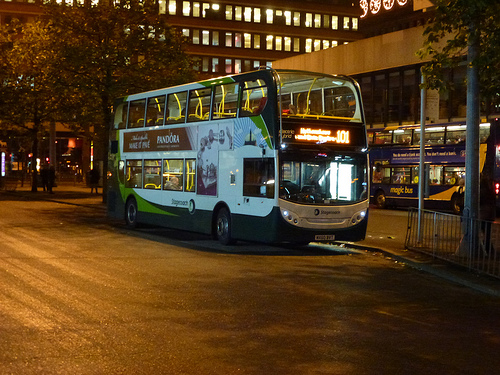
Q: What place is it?
A: It is a road.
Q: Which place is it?
A: It is a road.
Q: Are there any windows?
A: Yes, there is a window.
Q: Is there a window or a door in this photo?
A: Yes, there is a window.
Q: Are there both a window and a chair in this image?
A: No, there is a window but no chairs.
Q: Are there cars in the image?
A: No, there are no cars.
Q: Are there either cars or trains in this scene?
A: No, there are no cars or trains.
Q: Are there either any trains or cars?
A: No, there are no cars or trains.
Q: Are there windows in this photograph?
A: Yes, there is a window.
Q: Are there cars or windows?
A: Yes, there is a window.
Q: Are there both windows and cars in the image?
A: No, there is a window but no cars.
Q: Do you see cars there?
A: No, there are no cars.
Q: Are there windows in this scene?
A: Yes, there is a window.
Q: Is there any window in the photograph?
A: Yes, there is a window.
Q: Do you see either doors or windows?
A: Yes, there is a window.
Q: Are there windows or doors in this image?
A: Yes, there is a window.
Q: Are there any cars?
A: No, there are no cars.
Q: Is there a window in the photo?
A: Yes, there is a window.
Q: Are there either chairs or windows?
A: Yes, there is a window.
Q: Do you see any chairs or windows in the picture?
A: Yes, there is a window.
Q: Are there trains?
A: No, there are no trains.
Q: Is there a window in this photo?
A: Yes, there is a window.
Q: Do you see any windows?
A: Yes, there is a window.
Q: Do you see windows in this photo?
A: Yes, there is a window.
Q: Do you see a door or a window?
A: Yes, there is a window.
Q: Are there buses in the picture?
A: Yes, there is a bus.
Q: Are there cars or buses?
A: Yes, there is a bus.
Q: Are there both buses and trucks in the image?
A: No, there is a bus but no trucks.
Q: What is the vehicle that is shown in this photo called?
A: The vehicle is a bus.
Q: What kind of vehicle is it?
A: The vehicle is a bus.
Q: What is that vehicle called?
A: This is a bus.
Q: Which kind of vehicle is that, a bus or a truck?
A: This is a bus.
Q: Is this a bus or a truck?
A: This is a bus.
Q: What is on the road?
A: The bus is on the road.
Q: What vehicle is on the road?
A: The vehicle is a bus.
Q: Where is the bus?
A: The bus is on the road.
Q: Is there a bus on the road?
A: Yes, there is a bus on the road.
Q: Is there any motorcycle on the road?
A: No, there is a bus on the road.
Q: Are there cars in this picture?
A: No, there are no cars.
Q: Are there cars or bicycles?
A: No, there are no cars or bicycles.